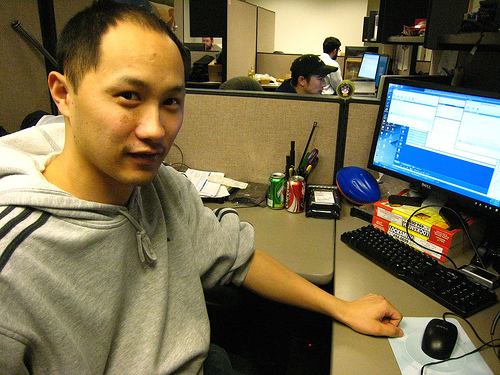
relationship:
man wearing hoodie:
[0, 1, 405, 371] [2, 120, 260, 373]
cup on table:
[286, 175, 307, 213] [201, 175, 500, 374]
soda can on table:
[264, 168, 288, 215] [201, 175, 500, 374]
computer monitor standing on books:
[364, 70, 499, 219] [369, 183, 492, 272]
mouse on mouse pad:
[418, 313, 462, 365] [384, 302, 499, 373]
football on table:
[332, 157, 385, 212] [201, 175, 500, 374]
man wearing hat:
[272, 47, 341, 102] [286, 50, 342, 83]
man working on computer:
[272, 47, 341, 102] [371, 62, 453, 106]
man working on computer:
[309, 32, 349, 94] [353, 49, 390, 89]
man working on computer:
[195, 37, 224, 54] [180, 39, 211, 55]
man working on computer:
[0, 1, 405, 371] [364, 72, 500, 243]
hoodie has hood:
[2, 120, 260, 373] [1, 105, 167, 271]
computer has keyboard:
[364, 72, 500, 243] [337, 215, 499, 329]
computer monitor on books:
[364, 70, 499, 219] [369, 183, 492, 272]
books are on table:
[369, 183, 492, 272] [201, 175, 500, 374]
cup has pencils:
[283, 170, 310, 212] [275, 116, 327, 174]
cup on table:
[283, 170, 310, 212] [201, 175, 500, 374]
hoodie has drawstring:
[2, 120, 260, 373] [119, 187, 168, 281]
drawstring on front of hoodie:
[119, 187, 168, 281] [2, 120, 260, 373]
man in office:
[0, 1, 405, 371] [0, 0, 499, 373]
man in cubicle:
[0, 1, 405, 371] [1, 70, 499, 374]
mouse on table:
[418, 313, 462, 365] [201, 175, 500, 374]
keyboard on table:
[337, 215, 499, 329] [201, 175, 500, 374]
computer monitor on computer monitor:
[369, 82, 499, 210] [364, 70, 499, 219]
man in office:
[272, 47, 341, 102] [0, 0, 499, 373]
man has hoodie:
[0, 1, 405, 371] [2, 120, 260, 373]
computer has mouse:
[364, 72, 500, 243] [418, 313, 462, 365]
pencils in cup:
[275, 116, 327, 174] [283, 170, 310, 212]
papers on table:
[177, 160, 250, 215] [201, 175, 500, 374]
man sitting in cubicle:
[0, 1, 405, 371] [1, 70, 499, 374]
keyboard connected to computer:
[337, 215, 499, 329] [364, 72, 500, 243]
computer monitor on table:
[364, 70, 499, 219] [201, 175, 500, 374]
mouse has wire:
[418, 313, 462, 365] [441, 306, 500, 352]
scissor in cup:
[303, 147, 321, 171] [283, 170, 310, 212]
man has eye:
[0, 1, 405, 371] [109, 84, 147, 114]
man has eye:
[0, 1, 405, 371] [158, 91, 184, 116]